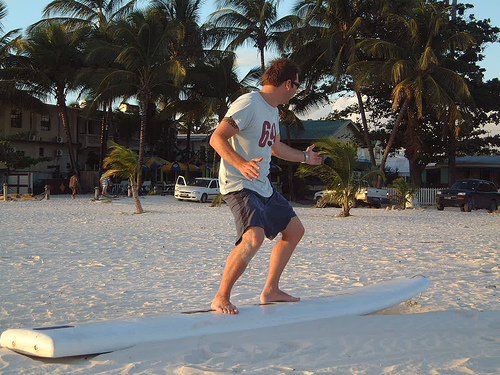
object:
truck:
[313, 179, 388, 209]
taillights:
[387, 191, 389, 197]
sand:
[389, 361, 498, 375]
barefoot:
[260, 288, 301, 303]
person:
[99, 173, 111, 198]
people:
[69, 172, 80, 200]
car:
[435, 179, 499, 213]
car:
[174, 175, 220, 203]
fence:
[382, 187, 449, 206]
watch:
[301, 151, 309, 164]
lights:
[364, 189, 369, 196]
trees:
[300, 1, 478, 187]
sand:
[400, 244, 462, 270]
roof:
[0, 79, 43, 109]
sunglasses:
[291, 82, 300, 89]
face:
[282, 83, 298, 104]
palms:
[1, 16, 99, 177]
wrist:
[299, 135, 310, 169]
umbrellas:
[158, 160, 202, 175]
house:
[0, 81, 112, 195]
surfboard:
[0, 276, 431, 359]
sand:
[413, 284, 483, 309]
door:
[175, 175, 187, 189]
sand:
[1, 195, 59, 258]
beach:
[0, 206, 499, 373]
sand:
[2, 359, 66, 369]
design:
[32, 325, 76, 331]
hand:
[306, 144, 322, 166]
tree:
[202, 0, 296, 82]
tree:
[85, 0, 188, 196]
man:
[209, 58, 323, 315]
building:
[0, 81, 178, 197]